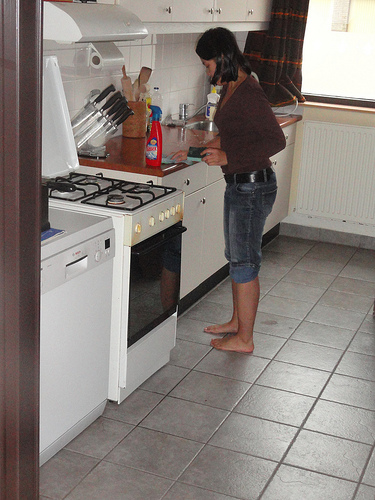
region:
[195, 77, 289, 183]
the shirt is brown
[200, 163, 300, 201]
the belt is black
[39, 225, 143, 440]
the dishwasher is white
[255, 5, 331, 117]
the curtain is brown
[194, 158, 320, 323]
the jeans are blue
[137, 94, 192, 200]
the cleaner is red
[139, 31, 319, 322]
woman cleaning the counter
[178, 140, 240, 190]
the sponge is green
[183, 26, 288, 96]
the hair is black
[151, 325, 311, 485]
the floor is tiled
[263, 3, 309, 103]
Brown and orange curtains in kitchen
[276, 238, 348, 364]
A few of the kitchen tiles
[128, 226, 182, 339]
Black oven in kitchen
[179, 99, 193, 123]
Silver sink faucet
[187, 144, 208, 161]
Light blue and green sponge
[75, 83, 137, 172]
Silver Knife folder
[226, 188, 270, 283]
Dark blue jeans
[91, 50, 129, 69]
Paper towel roll holder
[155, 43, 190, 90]
Wall tiles in the kitchen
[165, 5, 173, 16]
Knob of white cabinets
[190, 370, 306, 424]
gray tiles on the floor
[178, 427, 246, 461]
line in the gray tile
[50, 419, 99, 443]
white edge of the floor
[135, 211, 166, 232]
knob on the white stove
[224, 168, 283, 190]
black belt around woman's waist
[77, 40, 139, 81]
roll of white paper towel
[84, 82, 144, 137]
black edges of knives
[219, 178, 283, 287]
blue jean on woman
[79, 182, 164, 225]
black burner on stove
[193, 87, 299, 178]
brown long sleeve shirt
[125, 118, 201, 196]
woman uses sponge to clean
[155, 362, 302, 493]
bland large tiles cover the floor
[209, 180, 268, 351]
woman has rolled up her pants legs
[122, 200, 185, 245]
stains cover the front of the stove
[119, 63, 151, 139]
wooden cooking utensils stand in a crock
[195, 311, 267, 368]
bare feet on kitchen floor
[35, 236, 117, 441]
white washing machine next to stove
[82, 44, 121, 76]
white paper towel holder mounted to wall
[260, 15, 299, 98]
dark heavy curtains pulled to side of window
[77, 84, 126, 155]
knife block sitting on counter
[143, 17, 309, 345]
woman cleaning kitchen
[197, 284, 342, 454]
large gray tiles on kitchen floor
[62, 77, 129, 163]
silver and black knife set on countertop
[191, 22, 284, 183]
woman wearing dark red sweater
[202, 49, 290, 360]
woman with jeans rolled up on lower legs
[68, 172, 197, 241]
knobs on stove have some discoloration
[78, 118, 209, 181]
counter top in reddish orage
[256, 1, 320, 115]
kitchen curtains are brown with orange stripe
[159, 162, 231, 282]
lower kitchen cabinets are white with silver knobs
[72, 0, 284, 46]
upper kitchen cabinets are white with silver knobs